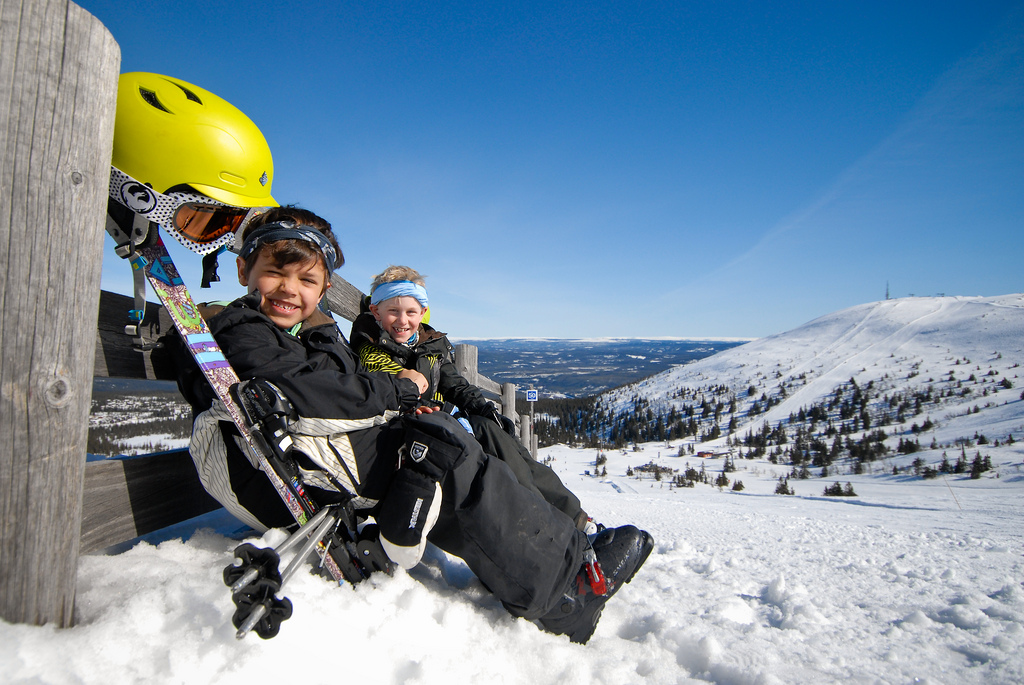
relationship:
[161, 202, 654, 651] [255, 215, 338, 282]
boy wearing bandanna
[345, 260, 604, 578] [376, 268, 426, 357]
boy wearing bandanna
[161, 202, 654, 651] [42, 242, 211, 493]
boy against fence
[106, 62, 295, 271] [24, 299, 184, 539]
helmet on fence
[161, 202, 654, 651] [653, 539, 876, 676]
boy in snow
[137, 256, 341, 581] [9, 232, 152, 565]
ski pole on fence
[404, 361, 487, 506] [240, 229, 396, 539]
gloves on boy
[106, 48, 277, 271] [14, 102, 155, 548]
helmet on fence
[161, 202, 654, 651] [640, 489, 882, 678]
boy in snow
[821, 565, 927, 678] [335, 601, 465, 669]
snow covered with snow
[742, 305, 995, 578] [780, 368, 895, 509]
hillside covered with trees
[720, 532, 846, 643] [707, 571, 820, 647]
tracks in snow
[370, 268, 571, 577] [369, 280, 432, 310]
boy wearing bandanna